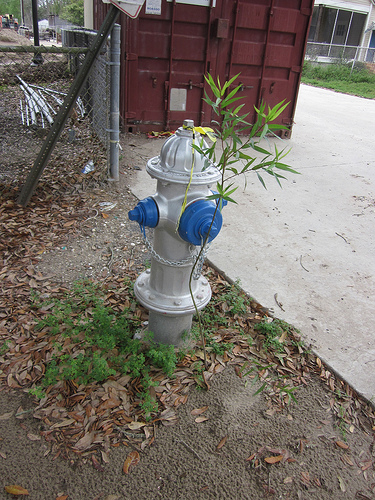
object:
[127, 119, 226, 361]
hydrant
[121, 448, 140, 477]
leaves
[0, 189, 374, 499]
ground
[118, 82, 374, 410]
driveway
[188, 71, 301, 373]
plant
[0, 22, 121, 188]
fence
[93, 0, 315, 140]
dumpster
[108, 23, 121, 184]
pole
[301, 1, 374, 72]
porch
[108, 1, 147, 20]
sign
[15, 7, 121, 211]
pipe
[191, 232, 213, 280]
chain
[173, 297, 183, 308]
bolts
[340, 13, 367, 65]
window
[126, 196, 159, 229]
plugs